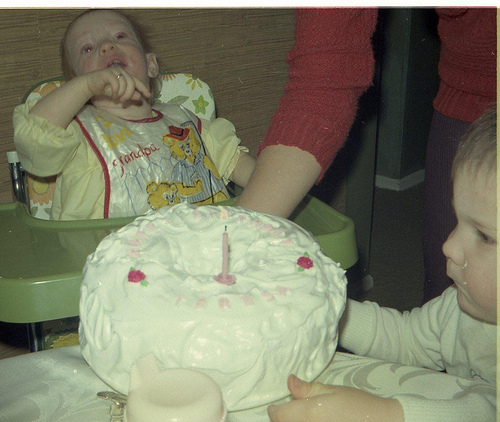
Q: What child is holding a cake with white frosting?
A: The child on the right.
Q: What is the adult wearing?
A: A sweater.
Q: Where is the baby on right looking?
A: Left.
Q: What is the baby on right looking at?
A: The cake.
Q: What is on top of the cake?
A: A candle.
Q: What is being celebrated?
A: A birthday.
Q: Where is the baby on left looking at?
A: Above.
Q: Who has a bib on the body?
A: Baby.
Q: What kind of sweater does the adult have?
A: Red.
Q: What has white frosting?
A: Cake.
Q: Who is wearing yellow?
A: Baby.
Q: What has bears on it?
A: Bib.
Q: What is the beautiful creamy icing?
A: Cake.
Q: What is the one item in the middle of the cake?
A: Candle.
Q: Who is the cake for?
A: Me the child.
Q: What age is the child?
A: One.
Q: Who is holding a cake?
A: A child.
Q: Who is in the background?
A: A baby.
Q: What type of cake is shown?
A: White birthday.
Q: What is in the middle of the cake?
A: A candle.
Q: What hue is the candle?
A: Pink.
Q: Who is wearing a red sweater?
A: The mother.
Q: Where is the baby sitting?
A: A highchair.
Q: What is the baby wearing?
A: A bib.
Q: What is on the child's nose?
A: Frosting.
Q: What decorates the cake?
A: Pink flowers.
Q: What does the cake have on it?
A: Candle.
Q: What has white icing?
A: Cake.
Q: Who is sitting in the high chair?
A: Baby.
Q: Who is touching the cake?
A: Child.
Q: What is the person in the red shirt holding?
A: Cake.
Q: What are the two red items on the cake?
A: Decorations.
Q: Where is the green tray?
A: High chair.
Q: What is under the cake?
A: Tablecloth.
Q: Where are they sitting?
A: At the table.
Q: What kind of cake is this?
A: A birthday cake.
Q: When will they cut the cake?
A: After her wish.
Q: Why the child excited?
A: Her birthday.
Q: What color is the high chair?
A: Its green.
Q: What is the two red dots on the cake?
A: The eyes.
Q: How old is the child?
A: One year old.